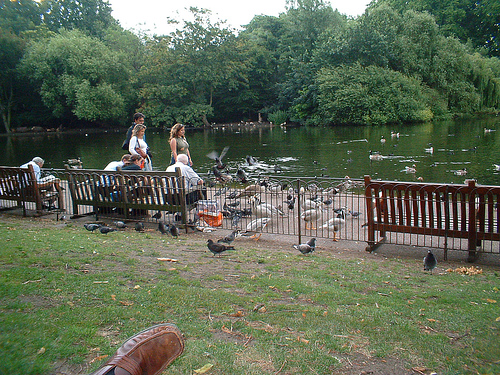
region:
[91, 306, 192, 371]
a penny loafer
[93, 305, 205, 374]
a brown leather shoe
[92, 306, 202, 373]
a brown leather penny loafer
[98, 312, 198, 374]
brown penny loafer shoe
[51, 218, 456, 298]
there are pigeons on the ground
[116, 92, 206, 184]
people walking in a park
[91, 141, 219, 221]
people sitting on a bench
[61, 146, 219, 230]
three people on a wooden park bench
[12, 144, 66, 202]
an old man on a park bench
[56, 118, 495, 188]
a small lake in a park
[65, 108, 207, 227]
people by a pond in the park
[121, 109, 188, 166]
people walking by the pond in the park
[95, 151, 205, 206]
people sitting on the bench by the pond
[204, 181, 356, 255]
lot of bird on side walk and grass by the pond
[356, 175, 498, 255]
wooden bench on sidewalk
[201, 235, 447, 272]
three pigions in the grass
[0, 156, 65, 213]
elderly man sitting on bench by the pond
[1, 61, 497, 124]
trees across the water of the pond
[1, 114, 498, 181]
large pond with many ducks in it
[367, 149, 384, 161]
duck sitting on the water of the pond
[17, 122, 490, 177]
a duck pond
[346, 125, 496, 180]
ducks in the water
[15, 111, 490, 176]
water is reflecting a green color from the trees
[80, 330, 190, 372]
a brown shoe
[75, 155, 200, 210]
people sitting down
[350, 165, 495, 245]
a bench for people to sit on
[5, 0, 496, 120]
trees around the duck pond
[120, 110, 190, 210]
people walking around a duck pond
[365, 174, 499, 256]
The bench is a brown color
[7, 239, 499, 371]
The ground is green and brown with grass and dirt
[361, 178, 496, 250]
brown wooden park bench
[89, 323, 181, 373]
man's brown shoe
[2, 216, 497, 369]
grass covered ground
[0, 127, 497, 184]
large lake in the park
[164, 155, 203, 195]
old man feeding the ducks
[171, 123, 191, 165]
brown haired woman walking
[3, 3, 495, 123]
large trees behind the lake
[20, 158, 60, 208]
man reading in the park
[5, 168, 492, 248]
metal park fence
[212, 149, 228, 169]
bird flying out of the water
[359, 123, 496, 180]
ducks swimming in lake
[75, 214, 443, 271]
pigeons eating on grass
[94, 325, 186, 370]
brown leather men's shoe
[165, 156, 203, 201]
man wearing white shirt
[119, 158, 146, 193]
man wearing black shirt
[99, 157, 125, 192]
man wearing gray shirt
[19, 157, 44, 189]
man wearing blue shirt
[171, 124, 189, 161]
woman wearing green shirt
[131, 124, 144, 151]
woman wearing white shirt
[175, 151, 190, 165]
man has white hair